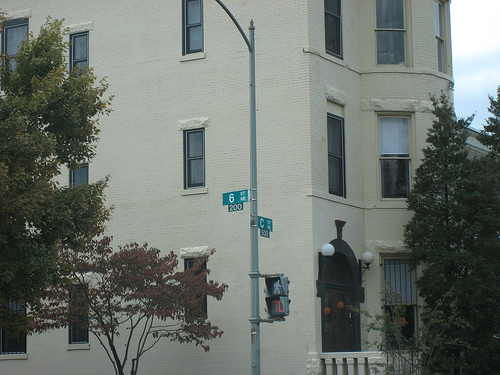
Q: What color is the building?
A: Creme.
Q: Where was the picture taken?
A: Canada.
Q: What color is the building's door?
A: Black.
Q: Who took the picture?
A: The property owner.